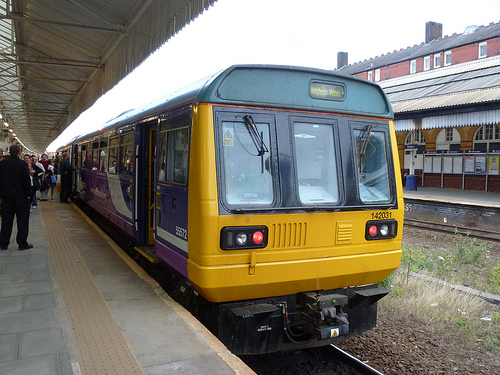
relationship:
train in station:
[50, 61, 412, 349] [3, 3, 495, 373]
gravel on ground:
[385, 320, 452, 372] [390, 332, 440, 365]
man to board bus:
[54, 148, 80, 208] [45, 53, 412, 340]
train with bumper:
[54, 61, 406, 357] [216, 259, 391, 291]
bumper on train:
[216, 259, 391, 291] [54, 61, 406, 357]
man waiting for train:
[0, 144, 34, 251] [50, 61, 412, 349]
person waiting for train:
[45, 159, 57, 201] [50, 61, 412, 349]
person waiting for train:
[22, 153, 37, 192] [50, 61, 412, 349]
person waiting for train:
[28, 151, 45, 196] [50, 61, 412, 349]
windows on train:
[46, 131, 136, 181] [61, 58, 404, 309]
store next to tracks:
[406, 108, 496, 189] [402, 217, 500, 243]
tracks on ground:
[391, 201, 499, 301] [318, 225, 499, 372]